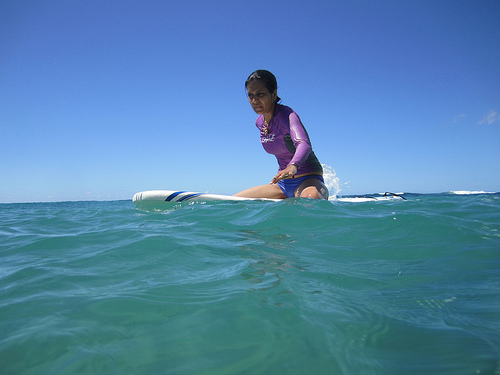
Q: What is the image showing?
A: It is showing an ocean.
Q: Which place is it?
A: It is an ocean.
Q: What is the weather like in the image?
A: It is cloudless.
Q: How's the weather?
A: It is cloudless.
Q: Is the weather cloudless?
A: Yes, it is cloudless.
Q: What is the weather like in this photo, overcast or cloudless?
A: It is cloudless.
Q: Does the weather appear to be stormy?
A: No, it is cloudless.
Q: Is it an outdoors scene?
A: Yes, it is outdoors.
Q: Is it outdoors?
A: Yes, it is outdoors.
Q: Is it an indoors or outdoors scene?
A: It is outdoors.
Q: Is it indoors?
A: No, it is outdoors.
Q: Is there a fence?
A: No, there are no fences.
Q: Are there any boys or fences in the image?
A: No, there are no fences or boys.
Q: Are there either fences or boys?
A: No, there are no fences or boys.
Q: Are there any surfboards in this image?
A: Yes, there is a surfboard.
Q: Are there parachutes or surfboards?
A: Yes, there is a surfboard.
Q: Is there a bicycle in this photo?
A: No, there are no bicycles.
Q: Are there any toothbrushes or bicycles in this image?
A: No, there are no bicycles or toothbrushes.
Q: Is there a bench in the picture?
A: No, there are no benches.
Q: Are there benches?
A: No, there are no benches.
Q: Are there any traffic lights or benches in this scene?
A: No, there are no benches or traffic lights.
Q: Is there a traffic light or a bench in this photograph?
A: No, there are no benches or traffic lights.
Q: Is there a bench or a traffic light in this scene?
A: No, there are no benches or traffic lights.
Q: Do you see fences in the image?
A: No, there are no fences.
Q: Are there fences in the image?
A: No, there are no fences.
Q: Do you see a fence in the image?
A: No, there are no fences.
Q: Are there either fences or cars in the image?
A: No, there are no fences or cars.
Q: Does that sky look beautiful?
A: Yes, the sky is beautiful.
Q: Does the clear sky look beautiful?
A: Yes, the sky is beautiful.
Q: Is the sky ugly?
A: No, the sky is beautiful.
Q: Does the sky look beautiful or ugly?
A: The sky is beautiful.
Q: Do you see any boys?
A: No, there are no boys.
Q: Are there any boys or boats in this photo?
A: No, there are no boys or boats.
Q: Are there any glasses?
A: No, there are no glasses.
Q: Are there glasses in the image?
A: No, there are no glasses.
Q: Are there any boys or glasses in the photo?
A: No, there are no glasses or boys.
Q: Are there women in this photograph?
A: Yes, there is a woman.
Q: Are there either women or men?
A: Yes, there is a woman.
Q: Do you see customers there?
A: No, there are no customers.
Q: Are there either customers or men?
A: No, there are no customers or men.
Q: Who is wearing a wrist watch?
A: The woman is wearing a wrist watch.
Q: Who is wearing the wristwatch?
A: The woman is wearing a wrist watch.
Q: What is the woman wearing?
A: The woman is wearing a wristwatch.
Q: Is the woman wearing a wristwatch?
A: Yes, the woman is wearing a wristwatch.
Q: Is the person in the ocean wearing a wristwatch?
A: Yes, the woman is wearing a wristwatch.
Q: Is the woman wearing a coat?
A: No, the woman is wearing a wristwatch.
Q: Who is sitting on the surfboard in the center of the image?
A: The woman is sitting on the surfboard.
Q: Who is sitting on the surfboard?
A: The woman is sitting on the surfboard.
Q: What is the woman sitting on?
A: The woman is sitting on the surfboard.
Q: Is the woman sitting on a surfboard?
A: Yes, the woman is sitting on a surfboard.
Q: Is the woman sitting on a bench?
A: No, the woman is sitting on a surfboard.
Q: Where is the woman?
A: The woman is in the ocean.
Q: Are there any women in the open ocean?
A: Yes, there is a woman in the ocean.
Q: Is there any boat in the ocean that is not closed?
A: No, there is a woman in the ocean.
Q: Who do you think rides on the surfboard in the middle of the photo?
A: The woman rides on the surfboard.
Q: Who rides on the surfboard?
A: The woman rides on the surfboard.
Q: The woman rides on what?
A: The woman rides on the surfboard.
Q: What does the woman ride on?
A: The woman rides on the surfboard.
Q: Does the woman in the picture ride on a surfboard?
A: Yes, the woman rides on a surfboard.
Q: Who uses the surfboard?
A: The woman uses the surfboard.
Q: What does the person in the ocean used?
A: The woman uses a surf board.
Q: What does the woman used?
A: The woman uses a surf board.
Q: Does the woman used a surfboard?
A: Yes, the woman uses a surfboard.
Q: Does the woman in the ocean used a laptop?
A: No, the woman uses a surfboard.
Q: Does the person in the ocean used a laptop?
A: No, the woman uses a surfboard.